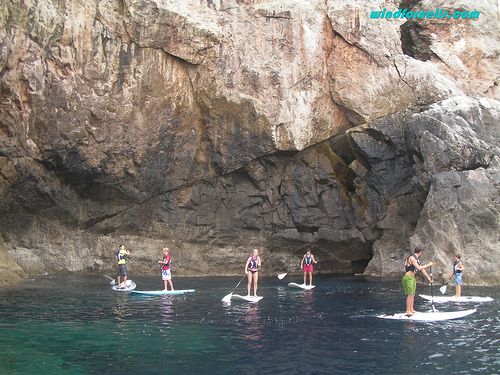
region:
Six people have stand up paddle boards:
[74, 212, 488, 339]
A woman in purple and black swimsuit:
[218, 231, 290, 336]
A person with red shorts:
[278, 234, 335, 312]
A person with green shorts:
[371, 243, 471, 338]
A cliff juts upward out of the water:
[21, 2, 483, 354]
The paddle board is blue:
[126, 246, 201, 303]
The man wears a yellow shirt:
[81, 224, 150, 313]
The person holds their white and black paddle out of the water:
[274, 229, 329, 298]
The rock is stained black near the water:
[23, 87, 435, 290]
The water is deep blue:
[58, 268, 470, 364]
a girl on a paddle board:
[220, 246, 271, 318]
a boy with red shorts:
[291, 240, 321, 285]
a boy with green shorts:
[378, 216, 429, 311]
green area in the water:
[36, 308, 238, 364]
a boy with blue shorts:
[449, 255, 467, 293]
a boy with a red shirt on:
[148, 240, 179, 270]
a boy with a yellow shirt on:
[105, 233, 148, 263]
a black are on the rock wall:
[325, 85, 439, 206]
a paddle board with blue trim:
[123, 286, 200, 298]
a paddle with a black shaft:
[277, 252, 316, 279]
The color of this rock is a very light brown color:
[407, 197, 444, 234]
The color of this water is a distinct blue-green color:
[217, 325, 253, 367]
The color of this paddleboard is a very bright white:
[444, 310, 459, 335]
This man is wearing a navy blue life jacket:
[301, 251, 324, 289]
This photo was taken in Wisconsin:
[70, 164, 467, 374]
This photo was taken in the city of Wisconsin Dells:
[81, 175, 441, 363]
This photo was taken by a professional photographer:
[75, 167, 477, 352]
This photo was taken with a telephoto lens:
[101, 175, 451, 371]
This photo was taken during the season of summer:
[87, 166, 449, 356]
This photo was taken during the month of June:
[108, 158, 450, 362]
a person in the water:
[103, 235, 141, 305]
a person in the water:
[154, 243, 185, 301]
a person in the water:
[231, 233, 273, 309]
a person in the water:
[283, 241, 320, 298]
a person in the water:
[388, 230, 437, 322]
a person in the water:
[440, 241, 477, 303]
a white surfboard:
[373, 295, 480, 332]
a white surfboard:
[419, 287, 493, 303]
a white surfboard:
[231, 289, 268, 308]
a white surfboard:
[287, 276, 315, 294]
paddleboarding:
[77, 219, 497, 353]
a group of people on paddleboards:
[103, 230, 485, 339]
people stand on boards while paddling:
[102, 233, 495, 342]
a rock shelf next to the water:
[26, 39, 491, 294]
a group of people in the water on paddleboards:
[96, 234, 498, 359]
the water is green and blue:
[26, 222, 484, 372]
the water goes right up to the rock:
[14, 241, 493, 308]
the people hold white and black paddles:
[103, 234, 474, 324]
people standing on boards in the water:
[81, 234, 496, 336]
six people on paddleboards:
[85, 231, 494, 343]